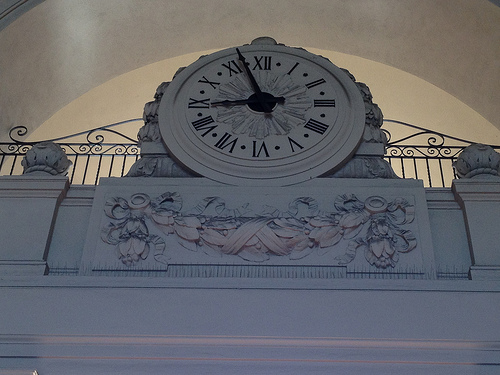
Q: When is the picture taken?
A: 8:56.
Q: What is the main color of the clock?
A: White.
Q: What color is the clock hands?
A: Black.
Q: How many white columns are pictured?
A: Two.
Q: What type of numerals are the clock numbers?
A: Roman.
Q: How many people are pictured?
A: None.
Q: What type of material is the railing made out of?
A: Metal.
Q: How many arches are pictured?
A: One.